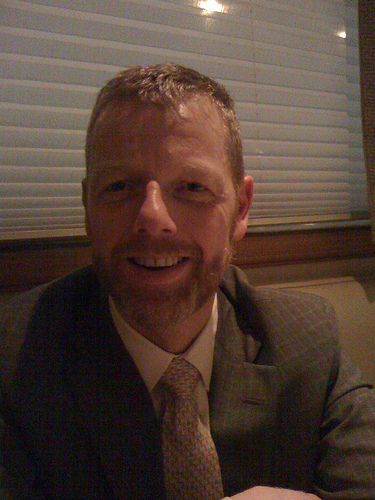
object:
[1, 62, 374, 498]
man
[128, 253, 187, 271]
teeth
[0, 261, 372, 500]
suit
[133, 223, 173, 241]
nostrils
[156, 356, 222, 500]
tie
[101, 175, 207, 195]
eyes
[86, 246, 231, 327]
beard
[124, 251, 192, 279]
mouth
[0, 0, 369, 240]
blinds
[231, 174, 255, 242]
ear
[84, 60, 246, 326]
head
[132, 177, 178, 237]
nose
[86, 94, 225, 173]
forehead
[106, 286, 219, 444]
shirt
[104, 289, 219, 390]
collar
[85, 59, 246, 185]
hair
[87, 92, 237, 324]
face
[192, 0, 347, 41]
light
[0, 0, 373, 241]
window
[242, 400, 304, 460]
suit lapel